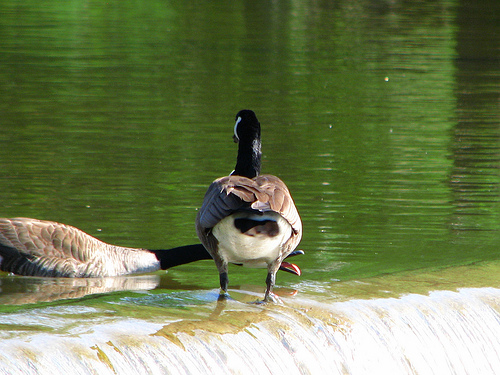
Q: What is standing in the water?
A: Duck.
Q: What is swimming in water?
A: A duck.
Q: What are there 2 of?
A: Ducks.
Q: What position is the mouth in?
A: Open.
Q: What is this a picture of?
A: Two ducks.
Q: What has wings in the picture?
A: Duck.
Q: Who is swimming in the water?
A: Duck.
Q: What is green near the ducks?
A: Water.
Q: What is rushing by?
A: Water.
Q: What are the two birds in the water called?
A: Geese.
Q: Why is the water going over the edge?
A: Mini waterfall.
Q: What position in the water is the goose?
A: Standing.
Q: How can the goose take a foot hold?
A: Cement under it.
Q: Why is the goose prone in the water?
A: Resting.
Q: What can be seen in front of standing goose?
A: Other's open mouth.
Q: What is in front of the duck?
A: Water.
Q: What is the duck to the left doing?
A: Swimming.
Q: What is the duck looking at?
A: Another duck.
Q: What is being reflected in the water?
A: Trees.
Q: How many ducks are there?
A: Two.